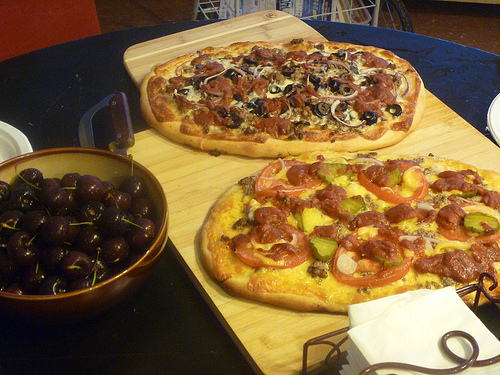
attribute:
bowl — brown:
[5, 141, 178, 313]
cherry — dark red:
[57, 168, 109, 209]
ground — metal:
[421, 133, 433, 147]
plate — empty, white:
[487, 93, 499, 143]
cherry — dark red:
[60, 246, 95, 286]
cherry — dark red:
[41, 211, 72, 246]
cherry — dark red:
[75, 170, 106, 202]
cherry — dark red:
[128, 213, 156, 247]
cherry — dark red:
[12, 166, 43, 187]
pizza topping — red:
[376, 198, 423, 235]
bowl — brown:
[9, 127, 149, 339]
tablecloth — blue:
[429, 41, 498, 98]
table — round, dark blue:
[7, 12, 492, 355]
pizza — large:
[193, 151, 498, 299]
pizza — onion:
[127, 37, 433, 162]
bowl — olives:
[0, 147, 167, 312]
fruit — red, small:
[8, 169, 149, 291]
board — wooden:
[115, 74, 499, 372]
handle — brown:
[110, 96, 132, 148]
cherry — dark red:
[42, 210, 75, 242]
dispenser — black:
[415, 300, 485, 356]